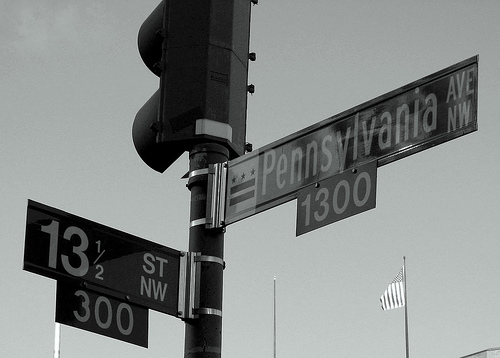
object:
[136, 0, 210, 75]
light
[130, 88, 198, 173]
lights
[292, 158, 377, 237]
sign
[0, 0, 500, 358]
sky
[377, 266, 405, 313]
flag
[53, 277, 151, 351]
signs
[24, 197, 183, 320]
directions